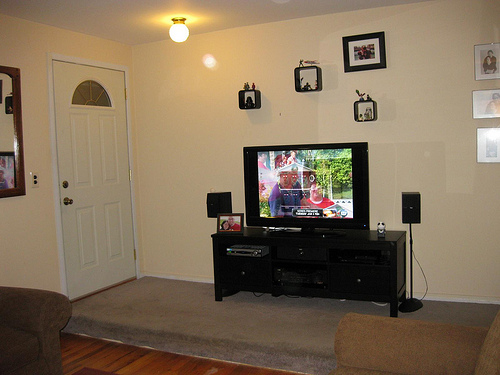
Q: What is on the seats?
A: Nothing.